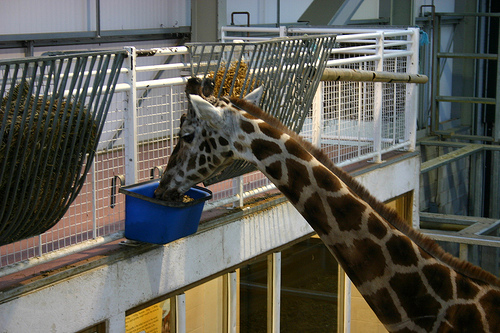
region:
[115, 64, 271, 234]
giraffe head having a drink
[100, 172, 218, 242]
blue water container on ledge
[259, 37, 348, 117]
metal container for food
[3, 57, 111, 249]
hay in a metal container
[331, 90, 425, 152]
white metal fence on side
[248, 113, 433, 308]
brown spots on giraffe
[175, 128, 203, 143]
left eye on the giraffe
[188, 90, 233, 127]
left ear on giraffe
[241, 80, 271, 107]
right ear on giraffe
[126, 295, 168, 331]
paper on the bottom of shelf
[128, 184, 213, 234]
the basket is blue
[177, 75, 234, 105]
the horns are two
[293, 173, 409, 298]
th spots are brown and white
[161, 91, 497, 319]
the giraffe is eating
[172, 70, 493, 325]
the giraffe is indoors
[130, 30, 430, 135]
the frame is mettalic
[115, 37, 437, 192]
the frame is white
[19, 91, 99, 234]
the grass is for the girafee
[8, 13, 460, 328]
is is daytime in the photo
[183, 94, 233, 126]
the ears are white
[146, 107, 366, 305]
This is a picture of a giraffe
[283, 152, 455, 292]
This is a long neck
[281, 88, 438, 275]
The giraffe is yellow and brown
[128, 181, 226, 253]
This is a picture of a blue bin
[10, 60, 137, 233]
This is a picture of a bird feeder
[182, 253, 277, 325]
This is a picture of a window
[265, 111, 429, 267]
This is brown fur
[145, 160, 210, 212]
This is a mouth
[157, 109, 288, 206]
This is a head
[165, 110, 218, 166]
This is a black eye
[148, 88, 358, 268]
The giraffe is eating.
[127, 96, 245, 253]
Giraffe head in blue bucket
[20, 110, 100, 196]
Hay in the steel feeders.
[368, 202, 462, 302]
The giraffe has brown spots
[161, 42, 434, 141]
A white fence around the top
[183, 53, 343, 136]
feeder attached to the fence.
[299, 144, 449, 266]
The giraffe is brown and white.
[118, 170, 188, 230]
The bucket is blue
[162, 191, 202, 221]
Food in the blue container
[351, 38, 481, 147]
Railing on the top stair.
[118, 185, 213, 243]
Blue plastic box with feed in it.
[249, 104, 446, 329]
The brown and white spotted neck of a giraffe.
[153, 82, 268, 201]
Brown and white head of a giraffe that is eating.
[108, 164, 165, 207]
Metal hooks on a blue feed bucket that hooks into the white railing.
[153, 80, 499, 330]
A brown and white giraffe eating.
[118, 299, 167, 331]
Orange sign under the blue feed bucket.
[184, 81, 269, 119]
White ears of a brown and white giraffe.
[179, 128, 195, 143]
Black eye of a brown and white giraffe.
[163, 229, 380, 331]
Windows under the giraffe.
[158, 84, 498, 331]
A brown and white giraffe that is eating.